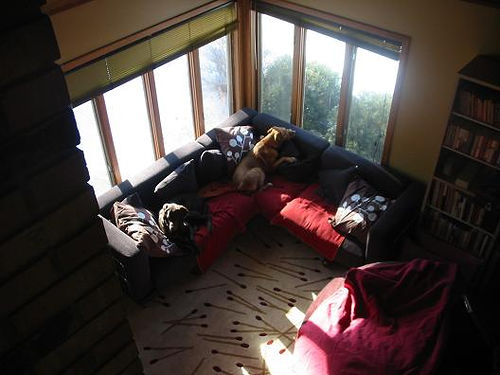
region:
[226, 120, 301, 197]
brown colored dog lying down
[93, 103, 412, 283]
couch with two dogs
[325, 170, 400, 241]
large brown pillow with blue design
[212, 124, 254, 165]
large brown pillow with blue design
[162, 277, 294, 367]
light colored rug with patterned design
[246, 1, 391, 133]
set of three windows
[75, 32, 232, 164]
set of four windows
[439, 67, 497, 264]
bookcase full of books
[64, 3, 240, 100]
open green window blind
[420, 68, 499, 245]
a book shelf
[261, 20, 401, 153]
a window behind the couch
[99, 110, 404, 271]
a couch in front of the window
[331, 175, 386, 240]
a pillow on the couch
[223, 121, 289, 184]
a brown dog laying on the couch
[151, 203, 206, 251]
a black dog laying on the couch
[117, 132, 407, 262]
two dogs on a couch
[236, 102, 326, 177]
a dog staring out the window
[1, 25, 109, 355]
a brick wall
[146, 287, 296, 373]
the carpet under the carpet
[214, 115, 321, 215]
a dog on a couch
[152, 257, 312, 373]
match stick pattern on rug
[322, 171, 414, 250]
a black pillow with blue flowers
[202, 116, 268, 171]
blue flowers on a pillow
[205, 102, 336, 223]
a brown dog on couch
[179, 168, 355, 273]
a red cover on couch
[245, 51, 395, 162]
two bushes outside window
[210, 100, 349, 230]
a dog looking out the window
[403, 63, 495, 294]
a shelf with many books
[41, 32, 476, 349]
a room in a home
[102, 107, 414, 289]
a black styled pit couch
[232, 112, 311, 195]
a brown dog on the couch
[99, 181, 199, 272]
pillows on the couch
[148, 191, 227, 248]
a barely noticeable blak dog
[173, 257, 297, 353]
a carpet with match stick designs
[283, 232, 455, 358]
a pink blanket over an object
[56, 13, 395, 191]
windows in the room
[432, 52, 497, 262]
a book case in the room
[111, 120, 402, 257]
couch in corner of room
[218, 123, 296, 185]
dog on the couch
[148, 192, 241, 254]
dog on the couch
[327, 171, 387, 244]
pillow on the couch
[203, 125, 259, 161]
pillow on the couch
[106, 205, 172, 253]
pillow on the couch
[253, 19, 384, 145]
window on the wall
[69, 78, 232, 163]
window on the wall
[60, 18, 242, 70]
blinds above the window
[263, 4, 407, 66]
blinds on the window